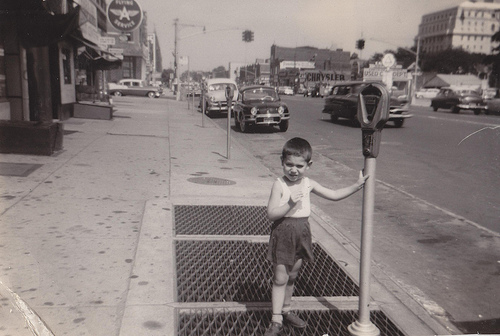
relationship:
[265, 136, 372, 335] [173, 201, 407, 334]
child standing on sidewalk grate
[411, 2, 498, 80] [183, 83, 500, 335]
building along side paved street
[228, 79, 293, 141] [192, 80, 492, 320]
car in street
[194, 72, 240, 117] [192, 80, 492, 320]
car in street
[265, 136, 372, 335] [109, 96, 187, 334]
child standing on sidewalk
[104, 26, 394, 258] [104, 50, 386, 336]
picture was taken years ago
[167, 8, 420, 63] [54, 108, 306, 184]
traffic lights in area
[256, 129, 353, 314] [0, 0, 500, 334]
child posing for a picture